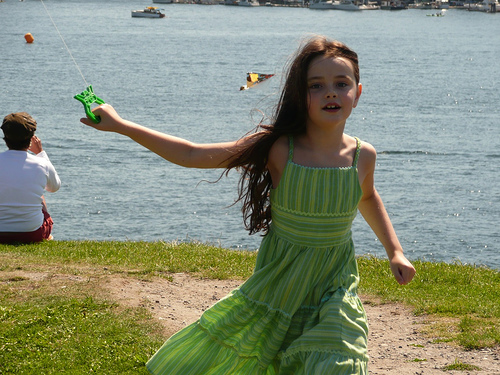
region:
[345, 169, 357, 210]
yellow stripe on dress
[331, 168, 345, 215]
yellow stripe on dress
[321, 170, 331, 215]
yellow stripe on dress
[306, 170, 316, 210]
yellow stripe on dress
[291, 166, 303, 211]
yellow stripe on dress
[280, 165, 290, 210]
yellow stripe on dress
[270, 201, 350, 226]
yellow stripe on dress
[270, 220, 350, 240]
yellow stripe on dress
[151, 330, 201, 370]
yellow stripe on dress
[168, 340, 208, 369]
yellow stripe on dress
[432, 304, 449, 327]
edge of a lawn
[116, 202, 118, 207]
edge of a sea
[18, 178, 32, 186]
part of a shirt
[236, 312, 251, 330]
edge of a dress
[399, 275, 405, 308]
part of a finger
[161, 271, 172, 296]
part of a grass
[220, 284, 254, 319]
edge of dress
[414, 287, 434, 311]
part of a lawn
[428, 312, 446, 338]
part of a grass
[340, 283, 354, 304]
part of a dress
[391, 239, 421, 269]
part of an arm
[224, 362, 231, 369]
edge of a dress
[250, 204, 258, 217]
part of an hair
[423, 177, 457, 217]
part of the sea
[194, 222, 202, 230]
part of a lake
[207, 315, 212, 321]
edge of a dress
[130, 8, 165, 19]
the boat on the water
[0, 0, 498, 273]
the body of water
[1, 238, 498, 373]
the grass near the girl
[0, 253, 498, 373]
the dirt near the girl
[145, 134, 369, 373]
the dress on the girl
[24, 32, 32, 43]
the buoy on the water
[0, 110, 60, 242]
the person sitting near the water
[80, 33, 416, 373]
the girl near the water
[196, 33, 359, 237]
the hair on the girl's head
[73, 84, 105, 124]
the green plastic in the girl's hand